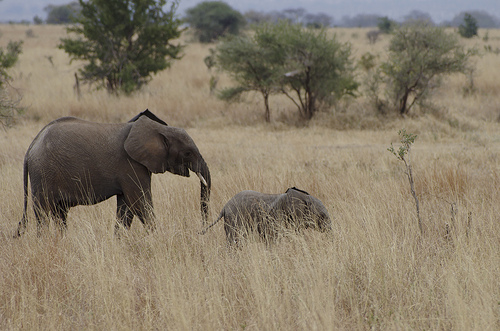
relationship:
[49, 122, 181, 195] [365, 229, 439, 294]
elephant in grass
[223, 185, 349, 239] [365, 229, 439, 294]
baby in grass